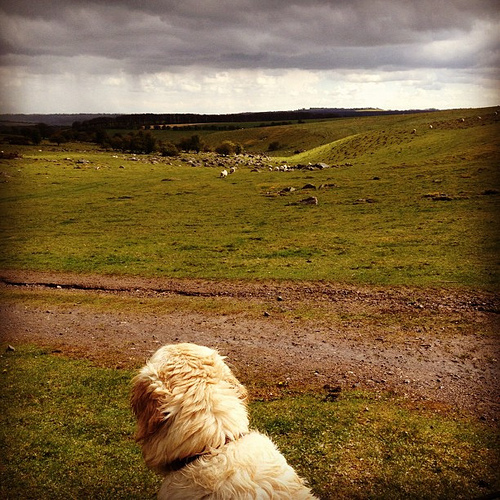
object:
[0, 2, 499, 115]
clouds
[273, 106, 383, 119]
plateau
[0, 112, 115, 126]
tree line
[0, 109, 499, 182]
animal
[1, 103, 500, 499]
field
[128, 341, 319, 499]
dog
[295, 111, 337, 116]
trees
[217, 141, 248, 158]
tree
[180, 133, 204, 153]
tree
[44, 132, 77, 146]
tree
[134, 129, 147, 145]
tree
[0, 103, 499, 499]
meadow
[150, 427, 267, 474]
collar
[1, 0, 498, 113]
sky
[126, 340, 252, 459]
head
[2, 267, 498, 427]
dirt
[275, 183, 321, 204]
stones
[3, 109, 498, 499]
grass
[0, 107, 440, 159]
forest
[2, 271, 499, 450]
dirt road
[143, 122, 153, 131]
trees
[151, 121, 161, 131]
trees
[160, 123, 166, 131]
trees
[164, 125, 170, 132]
trees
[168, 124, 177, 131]
trees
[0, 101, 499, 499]
country side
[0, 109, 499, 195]
distance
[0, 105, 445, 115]
top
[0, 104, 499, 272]
hill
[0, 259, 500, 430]
path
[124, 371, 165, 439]
ear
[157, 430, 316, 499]
back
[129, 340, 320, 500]
fur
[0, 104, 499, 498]
land